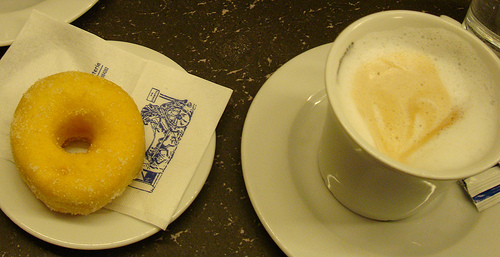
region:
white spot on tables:
[196, 56, 207, 63]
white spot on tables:
[201, 32, 211, 44]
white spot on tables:
[211, 24, 221, 34]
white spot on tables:
[219, 5, 231, 17]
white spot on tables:
[204, 8, 216, 18]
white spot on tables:
[181, 8, 200, 19]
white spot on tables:
[244, 0, 256, 10]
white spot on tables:
[237, 233, 252, 243]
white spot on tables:
[168, 228, 187, 242]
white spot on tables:
[203, 211, 215, 225]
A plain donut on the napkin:
[7, 73, 144, 209]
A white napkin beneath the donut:
[5, 13, 216, 215]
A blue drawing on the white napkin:
[124, 90, 196, 187]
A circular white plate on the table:
[0, 40, 215, 248]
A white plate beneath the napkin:
[35, 212, 151, 249]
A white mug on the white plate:
[325, 8, 499, 230]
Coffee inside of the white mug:
[340, 28, 494, 173]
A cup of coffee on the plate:
[321, 8, 498, 240]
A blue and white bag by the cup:
[467, 171, 498, 204]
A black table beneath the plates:
[187, 9, 276, 68]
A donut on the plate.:
[3, 62, 222, 252]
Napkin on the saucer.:
[131, 63, 197, 174]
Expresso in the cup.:
[362, 37, 457, 168]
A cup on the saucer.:
[322, 33, 473, 251]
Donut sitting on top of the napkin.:
[10, 67, 156, 204]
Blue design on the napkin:
[136, 81, 194, 174]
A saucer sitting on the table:
[0, 36, 228, 229]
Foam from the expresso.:
[372, 40, 464, 161]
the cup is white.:
[308, 45, 378, 225]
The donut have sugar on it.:
[18, 142, 143, 215]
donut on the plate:
[5, 98, 145, 211]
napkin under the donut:
[61, 54, 172, 216]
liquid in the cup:
[335, 15, 481, 208]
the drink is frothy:
[332, 37, 487, 160]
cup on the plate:
[252, 58, 491, 226]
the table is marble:
[172, 18, 269, 60]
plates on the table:
[30, 25, 432, 216]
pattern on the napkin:
[102, 58, 172, 188]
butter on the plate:
[455, 139, 492, 221]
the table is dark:
[218, 177, 240, 227]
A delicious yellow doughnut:
[12, 69, 145, 219]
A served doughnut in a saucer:
[2, 40, 214, 249]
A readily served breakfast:
[0, 0, 498, 251]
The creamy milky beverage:
[305, 10, 498, 220]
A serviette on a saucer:
[0, 10, 235, 230]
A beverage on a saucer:
[241, 9, 493, 255]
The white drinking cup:
[314, 10, 498, 225]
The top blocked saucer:
[0, 0, 97, 49]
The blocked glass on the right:
[458, 0, 498, 50]